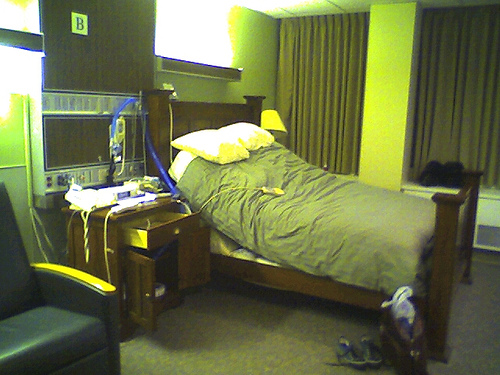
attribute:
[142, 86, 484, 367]
bed — brown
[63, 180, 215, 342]
desk — large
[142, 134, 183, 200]
breathing tube — blue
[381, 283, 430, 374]
bag — brown, leather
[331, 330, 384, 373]
shoes — casual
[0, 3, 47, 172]
lamp — small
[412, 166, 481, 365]
footboard — wooden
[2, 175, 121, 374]
chair — black, blue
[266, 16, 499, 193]
curtain — long, green, brown, pulled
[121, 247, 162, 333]
door — wooden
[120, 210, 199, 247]
drawer — open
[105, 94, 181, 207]
medical equipment — monitoring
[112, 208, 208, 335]
cabinet doors — open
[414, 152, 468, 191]
shoes — black